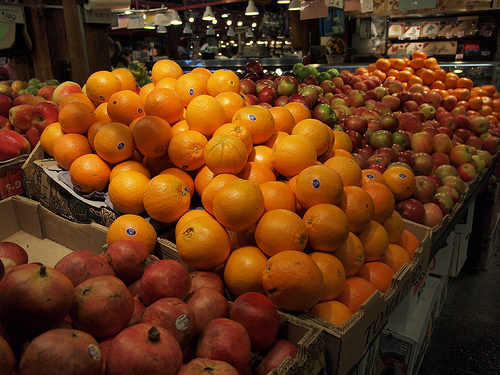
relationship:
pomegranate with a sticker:
[140, 293, 200, 355] [173, 312, 193, 332]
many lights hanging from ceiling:
[117, 0, 266, 41] [133, 2, 295, 7]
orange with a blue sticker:
[292, 161, 345, 209] [311, 178, 321, 189]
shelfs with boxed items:
[385, 15, 499, 60] [420, 17, 442, 41]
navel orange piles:
[92, 120, 138, 163] [59, 104, 276, 238]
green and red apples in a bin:
[370, 129, 416, 153] [347, 103, 499, 228]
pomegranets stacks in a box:
[0, 270, 221, 373] [0, 194, 333, 373]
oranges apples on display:
[109, 124, 348, 243] [38, 58, 421, 331]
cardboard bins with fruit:
[361, 188, 481, 374] [1, 61, 498, 226]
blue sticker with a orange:
[311, 178, 321, 189] [292, 161, 345, 209]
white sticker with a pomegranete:
[173, 312, 193, 332] [140, 293, 200, 355]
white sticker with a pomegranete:
[173, 312, 193, 332] [69, 274, 139, 342]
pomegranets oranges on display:
[0, 270, 221, 373] [0, 248, 326, 374]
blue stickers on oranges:
[311, 178, 321, 189] [109, 124, 348, 243]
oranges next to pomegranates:
[109, 124, 348, 243] [0, 270, 221, 373]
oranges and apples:
[109, 124, 348, 243] [347, 103, 499, 228]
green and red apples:
[370, 129, 416, 153] [347, 103, 499, 228]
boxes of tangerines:
[361, 188, 481, 374] [356, 49, 499, 107]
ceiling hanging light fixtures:
[133, 2, 295, 7] [117, 0, 266, 41]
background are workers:
[122, 39, 287, 60] [146, 34, 200, 62]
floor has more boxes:
[426, 276, 498, 373] [361, 188, 481, 374]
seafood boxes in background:
[385, 15, 499, 60] [289, 10, 497, 62]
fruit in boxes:
[1, 61, 498, 226] [361, 188, 481, 374]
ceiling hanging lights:
[133, 2, 295, 7] [117, 0, 266, 41]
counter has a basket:
[145, 57, 306, 70] [198, 41, 222, 60]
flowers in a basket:
[322, 38, 351, 56] [325, 52, 348, 66]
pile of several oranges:
[38, 58, 421, 331] [109, 124, 348, 243]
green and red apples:
[289, 63, 340, 84] [417, 121, 495, 226]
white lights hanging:
[202, 16, 219, 22] [117, 0, 266, 41]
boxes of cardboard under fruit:
[361, 188, 481, 374] [1, 61, 498, 226]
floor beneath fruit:
[426, 276, 498, 373] [38, 58, 421, 331]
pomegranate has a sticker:
[140, 293, 200, 355] [173, 312, 193, 332]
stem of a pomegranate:
[38, 263, 49, 279] [0, 259, 79, 333]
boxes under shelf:
[361, 188, 481, 374] [339, 234, 471, 343]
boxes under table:
[399, 292, 459, 355] [370, 243, 442, 321]